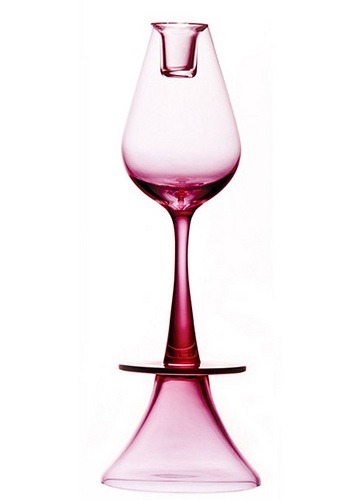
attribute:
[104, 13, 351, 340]
glass — shot, upside down, bowl, top, wine, clear, pink, here, shaped, tall, drinking, transparent, purple, standing, inlet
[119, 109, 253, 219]
gobletq — pink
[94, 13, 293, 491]
glasses — stacked, pink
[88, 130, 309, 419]
goblet — stemmed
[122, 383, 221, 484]
bottom — thick, squared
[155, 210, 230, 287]
stem — clear, here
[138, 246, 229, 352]
middle — darker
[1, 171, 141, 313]
background — white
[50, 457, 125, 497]
floor — white